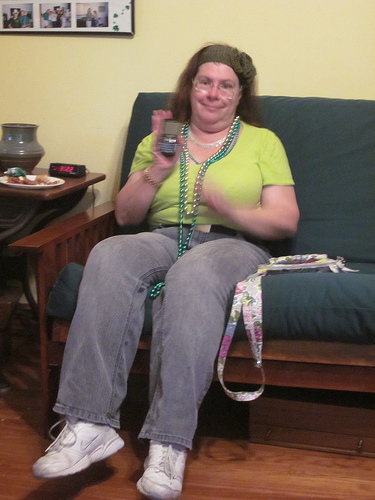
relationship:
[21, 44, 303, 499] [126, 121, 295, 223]
lady wearing shirt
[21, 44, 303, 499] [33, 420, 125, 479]
lady wearing shadow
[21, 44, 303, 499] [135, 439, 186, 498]
lady wearing shoe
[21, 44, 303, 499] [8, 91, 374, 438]
lady sitting on futon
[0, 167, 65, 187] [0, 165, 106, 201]
plate sitting on brown table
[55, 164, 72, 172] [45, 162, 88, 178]
numbers on clock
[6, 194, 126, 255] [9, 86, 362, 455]
arm on couch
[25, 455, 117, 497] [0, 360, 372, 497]
shadow on floor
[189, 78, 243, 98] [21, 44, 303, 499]
eyeglass on lady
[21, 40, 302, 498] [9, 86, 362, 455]
lady sitting on couch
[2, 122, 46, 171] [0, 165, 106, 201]
vase on brown table